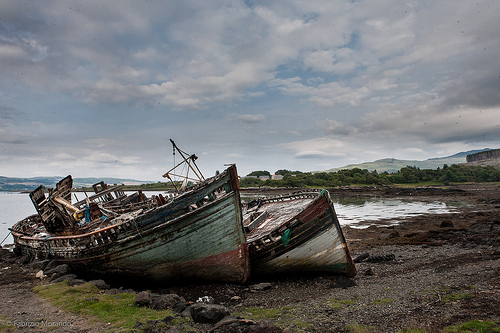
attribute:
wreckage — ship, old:
[26, 152, 384, 294]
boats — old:
[22, 160, 373, 296]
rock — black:
[177, 293, 238, 324]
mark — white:
[318, 241, 357, 266]